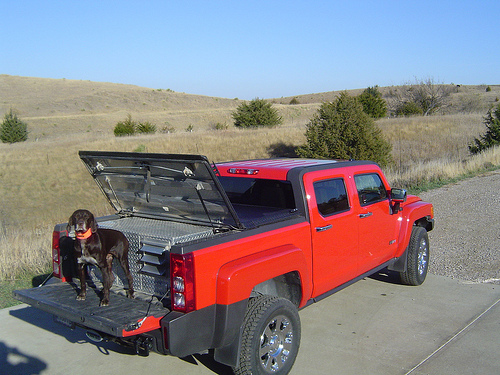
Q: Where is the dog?
A: On back of truck.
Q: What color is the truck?
A: Red.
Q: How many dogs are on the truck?
A: 1.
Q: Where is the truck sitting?
A: On a road.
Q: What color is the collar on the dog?
A: Orange.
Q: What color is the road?
A: Gray.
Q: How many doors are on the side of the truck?
A: 2.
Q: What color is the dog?
A: Black.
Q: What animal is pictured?
A: A dog.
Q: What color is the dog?
A: Black.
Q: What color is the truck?
A: Red.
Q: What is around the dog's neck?
A: A bandana.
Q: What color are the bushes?
A: Green.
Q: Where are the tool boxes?
A: In the back of the truck.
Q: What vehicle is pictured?
A: A truck.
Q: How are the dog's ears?
A: Floppy.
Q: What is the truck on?
A: Pavement.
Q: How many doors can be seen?
A: Two.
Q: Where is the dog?
A: In the back of the truck.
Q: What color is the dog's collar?
A: Orange.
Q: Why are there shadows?
A: Sunny.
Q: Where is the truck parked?
A: Driveway.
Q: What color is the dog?
A: Brown.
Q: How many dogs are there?
A: 1.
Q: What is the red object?
A: A truck.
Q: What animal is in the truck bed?
A: A dog.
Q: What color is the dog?
A: Brown.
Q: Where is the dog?
A: On the truck.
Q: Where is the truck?
A: On the pavement.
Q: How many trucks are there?
A: One.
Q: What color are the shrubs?
A: Green.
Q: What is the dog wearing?
A: A collar.